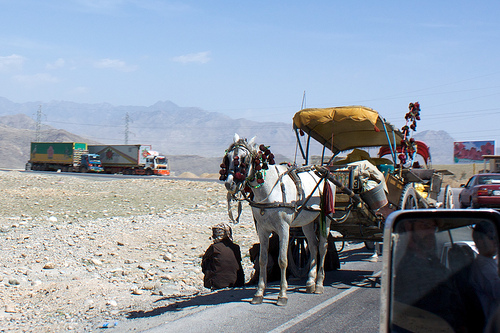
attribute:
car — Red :
[458, 168, 499, 209]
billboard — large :
[451, 137, 498, 167]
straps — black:
[218, 138, 325, 221]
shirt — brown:
[202, 241, 247, 286]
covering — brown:
[292, 101, 416, 153]